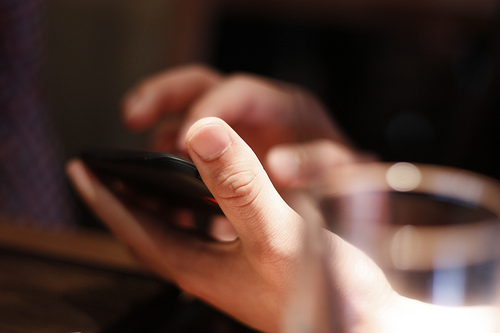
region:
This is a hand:
[57, 91, 359, 296]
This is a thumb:
[170, 106, 280, 219]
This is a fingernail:
[168, 116, 252, 162]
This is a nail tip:
[162, 103, 232, 133]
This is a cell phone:
[124, 105, 241, 230]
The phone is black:
[123, 155, 254, 202]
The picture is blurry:
[96, 122, 423, 302]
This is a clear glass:
[298, 134, 396, 311]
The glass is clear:
[348, 130, 485, 325]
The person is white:
[182, 152, 337, 297]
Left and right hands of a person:
[61, 66, 383, 331]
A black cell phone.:
[79, 145, 224, 212]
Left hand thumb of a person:
[184, 116, 293, 250]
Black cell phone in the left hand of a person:
[78, 144, 223, 214]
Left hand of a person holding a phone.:
[66, 115, 396, 332]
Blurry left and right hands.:
[63, 60, 382, 332]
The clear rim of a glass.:
[305, 155, 499, 305]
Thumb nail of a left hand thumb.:
[186, 121, 233, 159]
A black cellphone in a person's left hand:
[81, 147, 229, 217]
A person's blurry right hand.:
[116, 61, 381, 188]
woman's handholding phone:
[87, 117, 433, 331]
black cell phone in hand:
[54, 120, 244, 215]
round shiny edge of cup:
[309, 146, 494, 275]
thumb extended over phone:
[186, 122, 303, 255]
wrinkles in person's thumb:
[200, 170, 276, 209]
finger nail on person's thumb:
[174, 120, 249, 173]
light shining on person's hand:
[222, 170, 409, 330]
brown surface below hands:
[6, 202, 239, 323]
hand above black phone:
[92, 67, 375, 142]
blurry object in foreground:
[274, 162, 348, 322]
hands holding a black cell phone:
[61, 37, 452, 318]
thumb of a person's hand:
[182, 110, 296, 260]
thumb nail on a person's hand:
[187, 112, 244, 167]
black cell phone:
[79, 130, 243, 226]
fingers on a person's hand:
[142, 54, 333, 151]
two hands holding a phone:
[58, 47, 376, 313]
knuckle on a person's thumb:
[214, 165, 271, 213]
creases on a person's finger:
[219, 167, 275, 229]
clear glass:
[305, 139, 495, 299]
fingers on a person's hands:
[134, 59, 331, 209]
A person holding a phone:
[62, 69, 354, 284]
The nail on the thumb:
[182, 115, 241, 165]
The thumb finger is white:
[181, 114, 315, 256]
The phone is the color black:
[67, 115, 232, 229]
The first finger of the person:
[160, 65, 305, 152]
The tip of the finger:
[56, 151, 115, 210]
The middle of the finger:
[109, 190, 151, 258]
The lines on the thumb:
[218, 170, 273, 220]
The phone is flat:
[78, 110, 249, 234]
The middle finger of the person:
[111, 56, 218, 137]